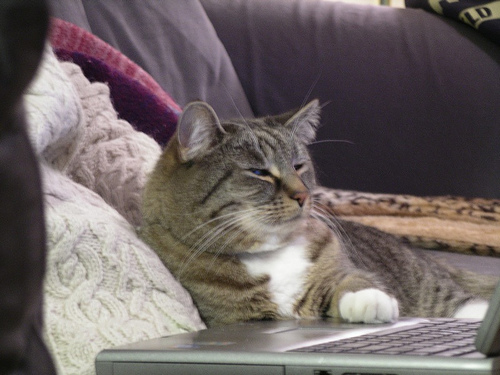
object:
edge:
[91, 350, 191, 366]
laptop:
[93, 278, 499, 375]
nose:
[286, 187, 311, 207]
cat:
[137, 71, 499, 328]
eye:
[243, 167, 271, 178]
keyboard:
[285, 316, 482, 356]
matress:
[314, 185, 499, 257]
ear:
[176, 100, 229, 163]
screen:
[473, 281, 499, 362]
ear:
[281, 98, 321, 141]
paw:
[338, 286, 400, 323]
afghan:
[22, 37, 208, 375]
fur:
[239, 233, 314, 319]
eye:
[290, 160, 308, 173]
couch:
[0, 0, 499, 375]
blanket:
[50, 17, 182, 150]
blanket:
[22, 39, 208, 375]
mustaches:
[169, 204, 279, 284]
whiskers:
[173, 203, 278, 277]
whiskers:
[309, 198, 357, 256]